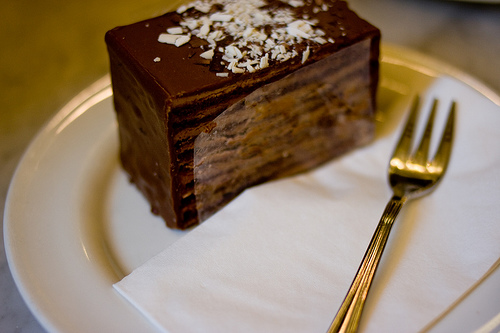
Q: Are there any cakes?
A: Yes, there is a cake.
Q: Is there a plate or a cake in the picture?
A: Yes, there is a cake.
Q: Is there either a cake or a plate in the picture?
A: Yes, there is a cake.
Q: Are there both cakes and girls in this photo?
A: No, there is a cake but no girls.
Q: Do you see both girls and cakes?
A: No, there is a cake but no girls.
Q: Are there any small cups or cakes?
A: Yes, there is a small cake.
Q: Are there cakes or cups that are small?
A: Yes, the cake is small.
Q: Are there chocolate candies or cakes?
A: Yes, there is a chocolate cake.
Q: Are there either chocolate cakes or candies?
A: Yes, there is a chocolate cake.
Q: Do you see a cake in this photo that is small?
A: Yes, there is a small cake.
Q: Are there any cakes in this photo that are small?
A: Yes, there is a cake that is small.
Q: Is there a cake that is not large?
A: Yes, there is a small cake.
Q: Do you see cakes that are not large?
A: Yes, there is a small cake.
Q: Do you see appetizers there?
A: No, there are no appetizers.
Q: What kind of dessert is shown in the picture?
A: The dessert is a cake.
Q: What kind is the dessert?
A: The dessert is a cake.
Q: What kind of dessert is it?
A: The dessert is a cake.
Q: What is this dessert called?
A: This is a cake.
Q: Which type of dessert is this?
A: This is a cake.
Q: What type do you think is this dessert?
A: This is a cake.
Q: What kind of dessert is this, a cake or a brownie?
A: This is a cake.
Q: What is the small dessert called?
A: The dessert is a cake.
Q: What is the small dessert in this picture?
A: The dessert is a cake.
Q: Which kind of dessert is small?
A: The dessert is a cake.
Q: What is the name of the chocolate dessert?
A: The dessert is a cake.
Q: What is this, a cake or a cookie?
A: This is a cake.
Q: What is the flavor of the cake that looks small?
A: This is a chocolate cake.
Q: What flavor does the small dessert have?
A: This is a chocolate cake.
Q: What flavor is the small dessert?
A: This is a chocolate cake.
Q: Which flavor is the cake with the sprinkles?
A: This is a chocolate cake.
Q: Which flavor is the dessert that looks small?
A: This is a chocolate cake.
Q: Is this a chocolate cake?
A: Yes, this is a chocolate cake.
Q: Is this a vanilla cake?
A: No, this is a chocolate cake.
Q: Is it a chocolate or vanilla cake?
A: This is a chocolate cake.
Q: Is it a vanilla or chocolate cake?
A: This is a chocolate cake.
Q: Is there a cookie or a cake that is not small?
A: No, there is a cake but it is small.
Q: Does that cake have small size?
A: Yes, the cake is small.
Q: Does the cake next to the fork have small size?
A: Yes, the cake is small.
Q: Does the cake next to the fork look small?
A: Yes, the cake is small.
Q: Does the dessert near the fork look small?
A: Yes, the cake is small.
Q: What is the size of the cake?
A: The cake is small.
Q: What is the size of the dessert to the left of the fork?
A: The cake is small.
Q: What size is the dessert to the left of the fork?
A: The cake is small.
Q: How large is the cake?
A: The cake is small.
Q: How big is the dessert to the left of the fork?
A: The cake is small.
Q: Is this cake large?
A: No, the cake is small.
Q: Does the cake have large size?
A: No, the cake is small.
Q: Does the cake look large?
A: No, the cake is small.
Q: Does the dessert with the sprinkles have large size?
A: No, the cake is small.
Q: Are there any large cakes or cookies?
A: No, there is a cake but it is small.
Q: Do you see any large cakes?
A: No, there is a cake but it is small.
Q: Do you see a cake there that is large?
A: No, there is a cake but it is small.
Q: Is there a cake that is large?
A: No, there is a cake but it is small.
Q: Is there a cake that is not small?
A: No, there is a cake but it is small.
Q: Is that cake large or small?
A: The cake is small.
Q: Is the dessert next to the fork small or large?
A: The cake is small.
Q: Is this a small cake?
A: Yes, this is a small cake.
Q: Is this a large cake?
A: No, this is a small cake.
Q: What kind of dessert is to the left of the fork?
A: The dessert is a cake.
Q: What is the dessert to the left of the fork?
A: The dessert is a cake.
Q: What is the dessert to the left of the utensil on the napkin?
A: The dessert is a cake.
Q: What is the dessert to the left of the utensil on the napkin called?
A: The dessert is a cake.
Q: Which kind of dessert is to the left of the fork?
A: The dessert is a cake.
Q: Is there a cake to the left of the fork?
A: Yes, there is a cake to the left of the fork.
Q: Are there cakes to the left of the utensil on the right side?
A: Yes, there is a cake to the left of the fork.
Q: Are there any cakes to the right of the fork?
A: No, the cake is to the left of the fork.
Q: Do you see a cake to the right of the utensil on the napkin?
A: No, the cake is to the left of the fork.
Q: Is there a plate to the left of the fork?
A: No, there is a cake to the left of the fork.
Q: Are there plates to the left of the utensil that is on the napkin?
A: No, there is a cake to the left of the fork.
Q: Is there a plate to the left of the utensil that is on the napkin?
A: No, there is a cake to the left of the fork.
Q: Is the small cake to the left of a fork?
A: Yes, the cake is to the left of a fork.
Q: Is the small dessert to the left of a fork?
A: Yes, the cake is to the left of a fork.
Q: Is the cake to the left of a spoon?
A: No, the cake is to the left of a fork.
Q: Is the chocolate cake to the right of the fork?
A: No, the cake is to the left of the fork.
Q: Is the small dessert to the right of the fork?
A: No, the cake is to the left of the fork.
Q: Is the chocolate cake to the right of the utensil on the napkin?
A: No, the cake is to the left of the fork.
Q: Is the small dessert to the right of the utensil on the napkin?
A: No, the cake is to the left of the fork.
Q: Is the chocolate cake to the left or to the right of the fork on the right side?
A: The cake is to the left of the fork.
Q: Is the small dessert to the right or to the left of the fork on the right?
A: The cake is to the left of the fork.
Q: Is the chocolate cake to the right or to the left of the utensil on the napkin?
A: The cake is to the left of the fork.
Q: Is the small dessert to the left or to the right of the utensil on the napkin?
A: The cake is to the left of the fork.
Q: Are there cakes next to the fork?
A: Yes, there is a cake next to the fork.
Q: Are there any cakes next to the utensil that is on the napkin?
A: Yes, there is a cake next to the fork.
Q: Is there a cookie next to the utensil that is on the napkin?
A: No, there is a cake next to the fork.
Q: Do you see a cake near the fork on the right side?
A: Yes, there is a cake near the fork.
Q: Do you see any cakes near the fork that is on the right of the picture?
A: Yes, there is a cake near the fork.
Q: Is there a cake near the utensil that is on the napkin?
A: Yes, there is a cake near the fork.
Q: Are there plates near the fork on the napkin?
A: No, there is a cake near the fork.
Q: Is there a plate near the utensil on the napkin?
A: No, there is a cake near the fork.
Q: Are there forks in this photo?
A: Yes, there is a fork.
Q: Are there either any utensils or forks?
A: Yes, there is a fork.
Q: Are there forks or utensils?
A: Yes, there is a fork.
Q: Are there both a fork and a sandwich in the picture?
A: No, there is a fork but no sandwiches.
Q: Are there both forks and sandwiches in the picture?
A: No, there is a fork but no sandwiches.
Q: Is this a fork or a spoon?
A: This is a fork.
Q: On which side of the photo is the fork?
A: The fork is on the right of the image.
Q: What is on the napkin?
A: The fork is on the napkin.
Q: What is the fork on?
A: The fork is on the napkin.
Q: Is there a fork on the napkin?
A: Yes, there is a fork on the napkin.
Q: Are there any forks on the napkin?
A: Yes, there is a fork on the napkin.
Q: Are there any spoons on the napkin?
A: No, there is a fork on the napkin.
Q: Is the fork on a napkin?
A: Yes, the fork is on a napkin.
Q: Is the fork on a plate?
A: No, the fork is on a napkin.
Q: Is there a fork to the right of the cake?
A: Yes, there is a fork to the right of the cake.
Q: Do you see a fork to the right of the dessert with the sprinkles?
A: Yes, there is a fork to the right of the cake.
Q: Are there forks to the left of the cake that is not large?
A: No, the fork is to the right of the cake.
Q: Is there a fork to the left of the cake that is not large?
A: No, the fork is to the right of the cake.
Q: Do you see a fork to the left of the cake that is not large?
A: No, the fork is to the right of the cake.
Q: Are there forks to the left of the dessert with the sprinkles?
A: No, the fork is to the right of the cake.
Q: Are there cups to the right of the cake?
A: No, there is a fork to the right of the cake.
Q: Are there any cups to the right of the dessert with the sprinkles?
A: No, there is a fork to the right of the cake.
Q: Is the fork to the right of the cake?
A: Yes, the fork is to the right of the cake.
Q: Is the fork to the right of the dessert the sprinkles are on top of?
A: Yes, the fork is to the right of the cake.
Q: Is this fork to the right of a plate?
A: No, the fork is to the right of the cake.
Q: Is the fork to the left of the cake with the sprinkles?
A: No, the fork is to the right of the cake.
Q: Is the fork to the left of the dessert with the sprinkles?
A: No, the fork is to the right of the cake.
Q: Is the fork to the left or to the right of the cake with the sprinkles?
A: The fork is to the right of the cake.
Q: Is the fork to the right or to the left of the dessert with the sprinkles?
A: The fork is to the right of the cake.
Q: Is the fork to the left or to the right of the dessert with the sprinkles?
A: The fork is to the right of the cake.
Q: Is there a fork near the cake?
A: Yes, there is a fork near the cake.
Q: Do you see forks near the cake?
A: Yes, there is a fork near the cake.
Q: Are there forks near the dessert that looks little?
A: Yes, there is a fork near the cake.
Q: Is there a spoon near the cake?
A: No, there is a fork near the cake.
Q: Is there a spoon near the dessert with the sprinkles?
A: No, there is a fork near the cake.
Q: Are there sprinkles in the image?
A: Yes, there are sprinkles.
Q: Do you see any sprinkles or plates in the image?
A: Yes, there are sprinkles.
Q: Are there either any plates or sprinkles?
A: Yes, there are sprinkles.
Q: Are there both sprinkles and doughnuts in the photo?
A: No, there are sprinkles but no donuts.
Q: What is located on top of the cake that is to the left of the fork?
A: The sprinkles are on top of the cake.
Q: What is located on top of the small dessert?
A: The sprinkles are on top of the cake.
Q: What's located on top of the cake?
A: The sprinkles are on top of the cake.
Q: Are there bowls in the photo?
A: No, there are no bowls.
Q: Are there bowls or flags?
A: No, there are no bowls or flags.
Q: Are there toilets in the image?
A: No, there are no toilets.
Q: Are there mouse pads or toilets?
A: No, there are no toilets or mouse pads.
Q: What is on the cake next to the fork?
A: The paper is on the cake.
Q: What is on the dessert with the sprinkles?
A: The paper is on the cake.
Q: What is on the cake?
A: The paper is on the cake.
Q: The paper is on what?
A: The paper is on the cake.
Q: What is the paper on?
A: The paper is on the cake.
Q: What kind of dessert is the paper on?
A: The paper is on the cake.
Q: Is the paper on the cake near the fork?
A: Yes, the paper is on the cake.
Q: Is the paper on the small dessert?
A: Yes, the paper is on the cake.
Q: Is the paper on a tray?
A: No, the paper is on the cake.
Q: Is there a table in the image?
A: Yes, there is a table.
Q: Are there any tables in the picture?
A: Yes, there is a table.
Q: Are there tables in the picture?
A: Yes, there is a table.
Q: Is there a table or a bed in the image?
A: Yes, there is a table.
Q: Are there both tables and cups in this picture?
A: No, there is a table but no cups.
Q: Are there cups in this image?
A: No, there are no cups.